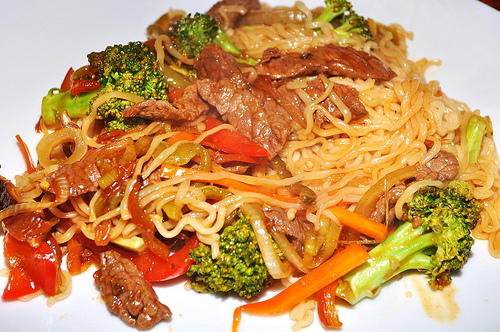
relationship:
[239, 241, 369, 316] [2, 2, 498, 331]
carrot on plate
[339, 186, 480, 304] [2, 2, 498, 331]
broccoli on plate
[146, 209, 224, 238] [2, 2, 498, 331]
noodle on plate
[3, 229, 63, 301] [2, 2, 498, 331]
pepper on plate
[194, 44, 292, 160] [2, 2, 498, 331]
beef on plate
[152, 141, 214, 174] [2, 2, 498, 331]
onion on plate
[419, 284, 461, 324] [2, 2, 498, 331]
sauce on plate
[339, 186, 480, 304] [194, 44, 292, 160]
broccoli and beef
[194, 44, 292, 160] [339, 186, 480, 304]
beef and broccoli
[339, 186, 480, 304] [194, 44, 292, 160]
broccoli with beef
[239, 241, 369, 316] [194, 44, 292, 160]
carrot with beef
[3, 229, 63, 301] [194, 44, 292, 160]
pepper with beef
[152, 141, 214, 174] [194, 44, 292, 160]
onion and beef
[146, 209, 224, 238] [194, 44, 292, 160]
noodle with beef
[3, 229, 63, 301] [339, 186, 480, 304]
pepper with broccoli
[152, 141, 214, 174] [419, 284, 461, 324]
onion with sauce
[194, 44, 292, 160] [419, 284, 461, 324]
beef and sauce